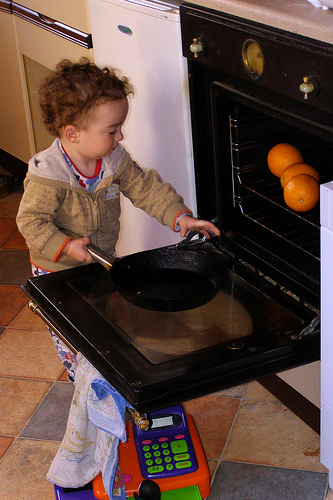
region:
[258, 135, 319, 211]
three oranges sitting on silver grate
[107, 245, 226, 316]
black cast iron skillet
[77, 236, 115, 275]
silver metal skillet handle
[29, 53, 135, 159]
child with curly brown hair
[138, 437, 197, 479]
buttons on toy of child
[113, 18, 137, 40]
silver emblem on dish washer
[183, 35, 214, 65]
white metal oven control knob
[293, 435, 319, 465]
stain on brown kitchen tile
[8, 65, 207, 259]
child in brown jacket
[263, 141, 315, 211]
three oranges in an oven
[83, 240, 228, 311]
a frying pan on an oven door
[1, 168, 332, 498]
a tile kitchen floor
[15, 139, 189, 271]
a light brown jacket on a toddler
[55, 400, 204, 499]
a plastic toy under an oven door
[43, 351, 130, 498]
a towel hanging on an oven door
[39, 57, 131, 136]
curly brown hair on a toddler's head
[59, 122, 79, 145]
the ear of a toddler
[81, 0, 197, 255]
a white dishwasher next to an oven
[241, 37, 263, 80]
a thermometer on the front of an oven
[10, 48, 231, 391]
toddler standing near an open oven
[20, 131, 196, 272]
toddlers brown jacket with orange lining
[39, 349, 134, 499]
toddlers blanket on door handle of stove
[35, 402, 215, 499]
childs cash register toy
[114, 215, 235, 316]
iron skillet on the open door of the stove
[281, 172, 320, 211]
orange in the stove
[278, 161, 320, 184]
orange in the stove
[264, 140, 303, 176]
orange in the stove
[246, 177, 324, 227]
rack in the oven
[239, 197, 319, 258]
rack in the oven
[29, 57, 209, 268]
a small kid puttin a pan in the oven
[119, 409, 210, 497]
a toy box is on the ground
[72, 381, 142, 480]
the table cloth is on the oven handle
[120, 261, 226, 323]
the pan is black in color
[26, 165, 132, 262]
the jackt is gray in color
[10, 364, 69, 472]
the floor is mae of tiles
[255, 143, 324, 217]
oranges are in the fridge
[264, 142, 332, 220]
they are orange incolor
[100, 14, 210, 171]
the fridge is next to th ee oven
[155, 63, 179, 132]
[part of a lioe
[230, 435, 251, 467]
part of a floor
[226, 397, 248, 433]
par tof a line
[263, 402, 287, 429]
part of a floor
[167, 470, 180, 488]
par tof a line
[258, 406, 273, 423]
part of a floor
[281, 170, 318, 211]
orange in the black oven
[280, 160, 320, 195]
orange in the black oven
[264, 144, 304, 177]
orange in the black oven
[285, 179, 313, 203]
orange in the oven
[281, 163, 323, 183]
orange in the oven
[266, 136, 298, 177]
orange in the oven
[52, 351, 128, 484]
towel on the oven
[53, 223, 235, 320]
child holding a black pan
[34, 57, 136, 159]
child with red hair